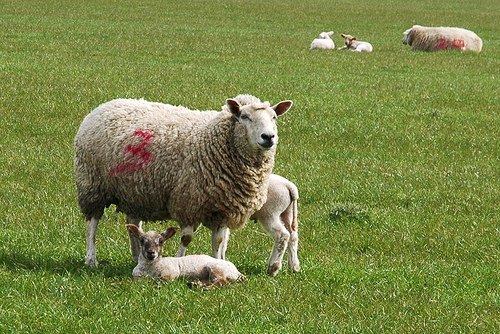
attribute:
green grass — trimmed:
[0, 0, 498, 330]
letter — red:
[102, 130, 157, 179]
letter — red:
[432, 33, 469, 57]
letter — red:
[113, 123, 165, 192]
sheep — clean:
[69, 89, 305, 296]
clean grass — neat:
[327, 75, 487, 319]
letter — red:
[109, 129, 156, 176]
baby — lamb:
[130, 226, 190, 274]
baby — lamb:
[253, 174, 290, 239]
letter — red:
[325, 201, 351, 224]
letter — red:
[103, 124, 179, 185]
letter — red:
[113, 130, 155, 172]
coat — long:
[72, 92, 277, 229]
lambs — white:
[303, 27, 375, 52]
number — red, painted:
[434, 33, 448, 50]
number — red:
[124, 128, 154, 178]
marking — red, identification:
[114, 121, 149, 177]